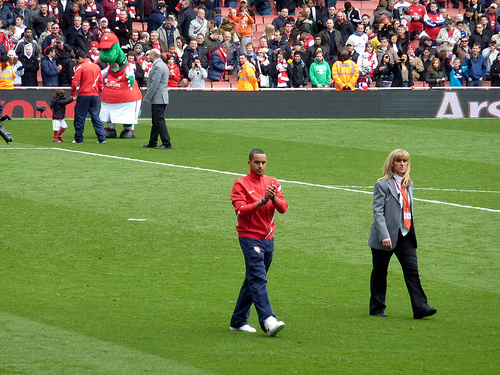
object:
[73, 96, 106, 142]
pants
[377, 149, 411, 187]
hair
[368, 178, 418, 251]
blazer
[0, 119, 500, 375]
field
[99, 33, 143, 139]
mascot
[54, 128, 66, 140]
socks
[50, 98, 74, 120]
hoodie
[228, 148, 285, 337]
man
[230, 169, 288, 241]
shirt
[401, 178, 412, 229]
tie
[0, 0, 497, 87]
people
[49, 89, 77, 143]
child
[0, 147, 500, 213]
markers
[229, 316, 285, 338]
shoes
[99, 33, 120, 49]
cap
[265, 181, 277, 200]
hands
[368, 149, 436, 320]
woman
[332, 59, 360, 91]
jacket